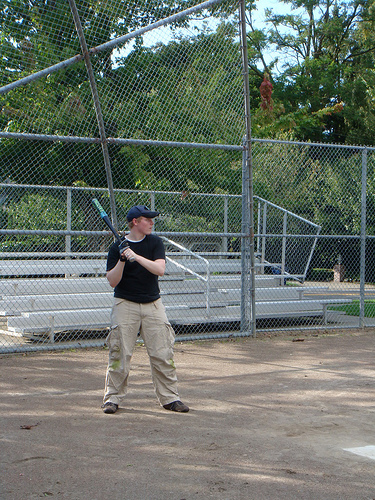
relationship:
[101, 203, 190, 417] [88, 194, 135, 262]
baseball player carrying a bat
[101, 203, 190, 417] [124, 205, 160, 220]
baseball player wearing a cap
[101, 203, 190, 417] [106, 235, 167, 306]
baseball player wearing a shirt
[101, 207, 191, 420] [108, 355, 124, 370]
baseball player has stain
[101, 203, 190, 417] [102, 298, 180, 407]
baseball player wearing cargo pants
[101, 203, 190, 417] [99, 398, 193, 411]
baseball player wearing brown shoes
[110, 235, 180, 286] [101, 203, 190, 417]
shirt on baseball player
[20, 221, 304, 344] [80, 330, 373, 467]
bleachers on field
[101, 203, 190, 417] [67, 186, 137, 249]
baseball player with bat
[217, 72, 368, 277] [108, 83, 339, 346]
trees with fence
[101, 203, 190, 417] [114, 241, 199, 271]
baseball player with shirt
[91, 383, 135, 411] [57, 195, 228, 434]
shoe on man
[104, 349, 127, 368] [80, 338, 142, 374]
stain on knee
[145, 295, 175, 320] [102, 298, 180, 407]
pocket on cargo pants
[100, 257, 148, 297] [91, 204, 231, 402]
elbow on man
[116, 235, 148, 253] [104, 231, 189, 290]
collar on shirt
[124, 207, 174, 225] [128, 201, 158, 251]
cap on head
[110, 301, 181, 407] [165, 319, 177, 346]
cargo pants provide pockets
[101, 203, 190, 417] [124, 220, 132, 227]
baseball player has hair